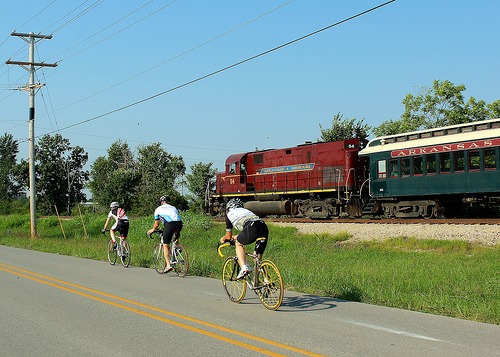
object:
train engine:
[213, 138, 368, 200]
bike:
[213, 234, 286, 310]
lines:
[0, 255, 329, 356]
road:
[0, 243, 499, 355]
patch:
[430, 252, 489, 301]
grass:
[0, 215, 498, 324]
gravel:
[264, 220, 500, 245]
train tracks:
[2, 211, 499, 226]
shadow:
[240, 292, 351, 312]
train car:
[356, 117, 500, 197]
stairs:
[358, 196, 379, 215]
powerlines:
[1, 1, 399, 154]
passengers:
[390, 163, 409, 176]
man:
[218, 197, 270, 288]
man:
[147, 194, 184, 272]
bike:
[146, 227, 190, 278]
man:
[101, 200, 129, 252]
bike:
[100, 225, 132, 267]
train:
[201, 118, 499, 217]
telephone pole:
[5, 29, 59, 239]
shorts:
[237, 219, 269, 253]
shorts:
[162, 219, 184, 244]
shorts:
[110, 219, 132, 239]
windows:
[385, 147, 495, 178]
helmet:
[225, 197, 246, 212]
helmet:
[159, 194, 172, 204]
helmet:
[110, 200, 120, 209]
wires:
[32, 43, 93, 242]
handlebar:
[216, 239, 234, 258]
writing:
[260, 162, 317, 175]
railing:
[253, 168, 358, 190]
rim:
[220, 256, 247, 302]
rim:
[253, 258, 284, 311]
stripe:
[211, 187, 339, 197]